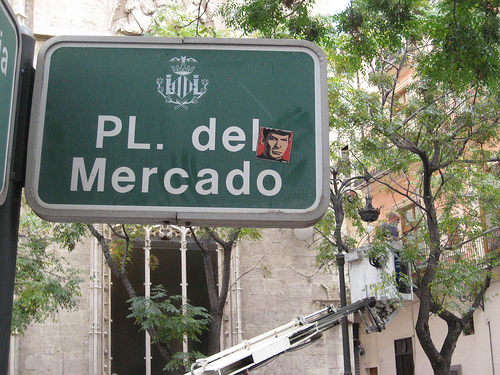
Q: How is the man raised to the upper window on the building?
A: Lifter on a truck.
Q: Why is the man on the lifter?
A: To rescue people on the upper level.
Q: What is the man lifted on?
A: A truck lifter.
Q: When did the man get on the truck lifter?
A: A weekday.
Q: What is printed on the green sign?
A: PL. del Mercado.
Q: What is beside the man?
A: Branches of a tree.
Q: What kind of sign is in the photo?
A: Street.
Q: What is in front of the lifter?
A: A metal fence.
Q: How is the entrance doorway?
A: Open.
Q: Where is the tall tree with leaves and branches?
A: To the right of the sign.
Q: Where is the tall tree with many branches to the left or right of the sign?
A: Right.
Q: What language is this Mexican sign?
A: Spanish.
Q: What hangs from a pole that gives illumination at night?
A: Light.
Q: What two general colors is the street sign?
A: Green and white.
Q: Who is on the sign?
A: Spock.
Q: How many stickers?
A: 1.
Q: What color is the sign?
A: Green.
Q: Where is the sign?
A: Next to the trees.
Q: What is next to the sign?
A: Building.